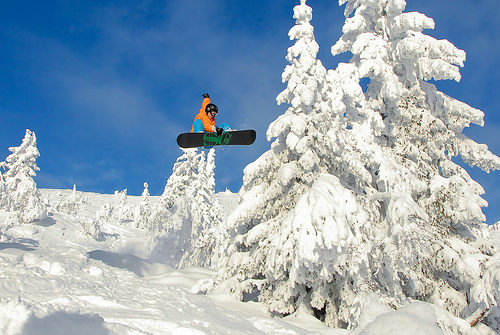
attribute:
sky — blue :
[1, 4, 341, 186]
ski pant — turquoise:
[188, 117, 222, 130]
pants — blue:
[184, 119, 233, 132]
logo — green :
[198, 128, 236, 149]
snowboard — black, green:
[176, 127, 259, 147]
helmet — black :
[199, 99, 230, 117]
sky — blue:
[2, 3, 282, 176]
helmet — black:
[204, 101, 219, 116]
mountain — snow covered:
[6, 119, 496, 329]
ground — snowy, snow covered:
[1, 192, 491, 333]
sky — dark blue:
[48, 38, 206, 147]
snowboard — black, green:
[176, 123, 274, 157]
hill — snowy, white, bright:
[1, 195, 451, 332]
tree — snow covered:
[326, 4, 498, 316]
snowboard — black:
[172, 127, 257, 152]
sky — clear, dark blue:
[4, 0, 498, 218]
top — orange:
[193, 95, 220, 127]